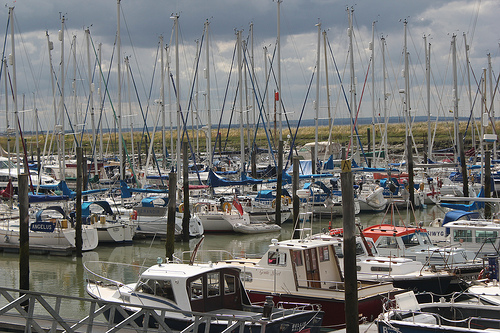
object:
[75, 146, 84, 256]
pole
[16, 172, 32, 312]
pole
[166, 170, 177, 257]
pole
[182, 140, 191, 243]
pole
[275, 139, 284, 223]
pole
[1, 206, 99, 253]
boat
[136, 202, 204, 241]
boat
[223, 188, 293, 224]
boat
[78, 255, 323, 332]
boat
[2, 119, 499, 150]
field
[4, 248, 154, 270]
water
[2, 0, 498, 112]
sky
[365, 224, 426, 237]
roof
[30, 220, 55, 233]
sign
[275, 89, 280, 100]
flag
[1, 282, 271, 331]
walkway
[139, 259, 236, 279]
roof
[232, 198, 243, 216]
flag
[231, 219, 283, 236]
dingy